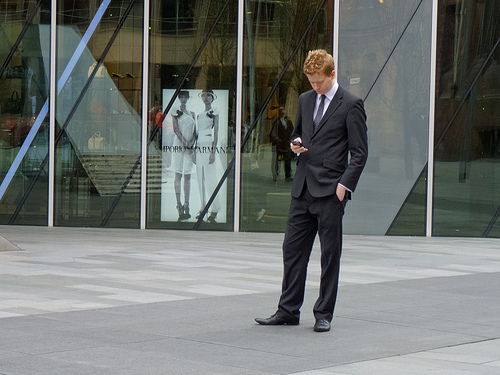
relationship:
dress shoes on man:
[251, 304, 334, 333] [255, 49, 367, 332]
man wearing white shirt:
[255, 49, 367, 332] [304, 80, 343, 134]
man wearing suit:
[255, 49, 367, 332] [268, 88, 370, 314]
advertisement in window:
[160, 88, 228, 224] [144, 0, 242, 228]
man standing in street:
[255, 49, 367, 332] [172, 339, 303, 373]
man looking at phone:
[255, 49, 367, 332] [289, 139, 306, 154]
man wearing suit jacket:
[255, 49, 367, 332] [291, 85, 369, 203]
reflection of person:
[267, 102, 300, 184] [255, 114, 322, 191]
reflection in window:
[267, 102, 300, 184] [155, 23, 382, 221]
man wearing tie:
[255, 49, 367, 332] [310, 93, 325, 133]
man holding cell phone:
[244, 24, 394, 373] [292, 141, 306, 149]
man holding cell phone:
[255, 49, 367, 332] [292, 131, 312, 158]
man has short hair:
[255, 49, 367, 332] [302, 50, 334, 75]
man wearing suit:
[255, 49, 367, 332] [276, 80, 368, 322]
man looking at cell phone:
[255, 49, 367, 332] [292, 141, 306, 149]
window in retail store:
[148, 4, 236, 227] [4, 1, 499, 234]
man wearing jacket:
[255, 49, 367, 332] [283, 83, 368, 200]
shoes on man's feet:
[249, 306, 336, 333] [249, 303, 333, 334]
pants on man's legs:
[269, 186, 354, 326] [276, 201, 345, 319]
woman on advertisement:
[194, 90, 226, 220] [160, 88, 228, 224]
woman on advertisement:
[169, 87, 196, 221] [160, 88, 228, 224]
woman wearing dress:
[169, 87, 196, 221] [172, 112, 196, 174]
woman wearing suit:
[194, 89, 226, 220] [192, 107, 220, 210]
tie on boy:
[311, 91, 328, 133] [255, 50, 371, 333]